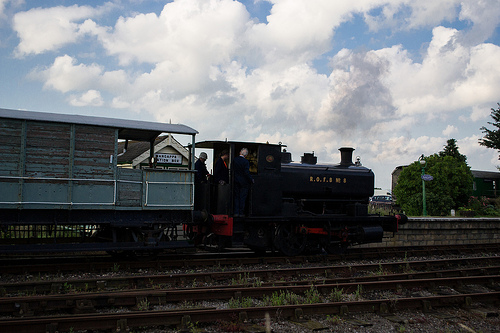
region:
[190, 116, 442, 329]
The front of the train is black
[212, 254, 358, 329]
The train is on a set of tracks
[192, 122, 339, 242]
There are men guiding the train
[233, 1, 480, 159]
The sky is full of clouds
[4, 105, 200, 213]
There is a second car behind the train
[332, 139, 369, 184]
A smoke stack in front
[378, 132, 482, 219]
A green round bush on side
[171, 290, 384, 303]
Grass is growing between track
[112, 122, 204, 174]
A window in the train car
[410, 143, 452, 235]
A light beside track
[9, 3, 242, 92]
clouds in the sky in lefthand side of photo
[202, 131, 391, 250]
Train engine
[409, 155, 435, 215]
street lamp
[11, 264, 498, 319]
empty railroad tracks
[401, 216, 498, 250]
brick wall dividing train area from buildings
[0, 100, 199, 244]
railcar following engine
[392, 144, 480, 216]
Large tree right of train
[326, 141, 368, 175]
smoke stack on engine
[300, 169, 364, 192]
Initials on the engine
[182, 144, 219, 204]
engineer running the train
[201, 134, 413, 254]
the train engine is black and red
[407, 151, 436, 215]
the light pole is green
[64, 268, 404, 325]
the railroad tracks are rusty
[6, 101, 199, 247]
one of the train box's has rust on it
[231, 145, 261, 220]
this man is wearing blue coverall's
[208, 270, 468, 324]
the tracks has grass growing up through them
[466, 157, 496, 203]
the building in the background is green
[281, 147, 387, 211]
the letters on the train engine is gold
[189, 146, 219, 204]
this man is wearing a white hat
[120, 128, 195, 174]
this building is white and green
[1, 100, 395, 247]
Train on a track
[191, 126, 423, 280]
The train is old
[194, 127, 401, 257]
The train is navy blue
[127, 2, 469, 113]
clouds in the sky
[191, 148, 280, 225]
Three people on the train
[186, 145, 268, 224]
The people are standing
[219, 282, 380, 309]
The green grass on the tracks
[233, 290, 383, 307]
The grass is growing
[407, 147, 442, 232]
A blue sign hanging on a pole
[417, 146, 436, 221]
The pole is green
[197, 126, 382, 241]
train engine is black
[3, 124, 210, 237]
train car is green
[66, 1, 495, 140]
skies are mostly clear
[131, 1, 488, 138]
some puffy clouds in sky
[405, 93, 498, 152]
small pine trees behind train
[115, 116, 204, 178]
white building behind train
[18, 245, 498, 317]
brown tracks in front of train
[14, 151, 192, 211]
white railing on train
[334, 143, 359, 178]
small smokestack on train engine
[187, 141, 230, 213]
conductor inside train engine